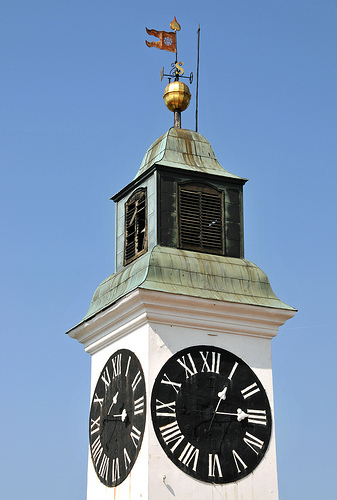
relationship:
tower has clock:
[71, 15, 271, 490] [132, 331, 289, 494]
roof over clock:
[57, 254, 291, 345] [132, 331, 289, 494]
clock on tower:
[132, 331, 289, 494] [71, 15, 271, 490]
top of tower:
[144, 16, 229, 147] [71, 15, 271, 490]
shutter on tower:
[118, 177, 258, 335] [71, 15, 271, 490]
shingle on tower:
[152, 68, 193, 135] [71, 15, 271, 490]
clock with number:
[132, 331, 289, 494] [180, 348, 257, 387]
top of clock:
[144, 16, 229, 147] [132, 331, 289, 494]